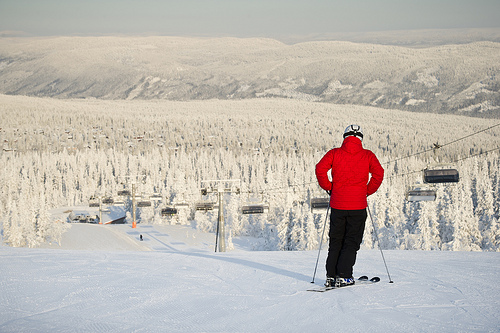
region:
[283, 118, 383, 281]
a person on skis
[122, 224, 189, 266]
a person in the distance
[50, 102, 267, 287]
a snow covered landscape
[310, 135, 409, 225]
a red jacket against the white of snow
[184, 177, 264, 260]
a ski lift in the distance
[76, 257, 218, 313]
fresh white snow on the ground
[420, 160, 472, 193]
a seat on the ski lift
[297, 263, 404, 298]
a pair of skis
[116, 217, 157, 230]
a splash of orange in the distance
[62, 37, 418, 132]
mountains in the distance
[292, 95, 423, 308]
man dressed in red skiing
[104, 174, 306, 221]
ski lift with chairs coming up hill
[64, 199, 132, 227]
ski lodge at bottom of the hill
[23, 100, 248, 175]
snow covered pine trees in the distance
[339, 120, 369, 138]
helmet on a skier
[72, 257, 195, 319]
ski tracks in the snow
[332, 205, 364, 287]
black snow pants on the skier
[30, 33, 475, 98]
snow covered mountain in the distance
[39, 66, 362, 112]
snow covered valley in the distance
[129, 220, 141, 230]
orange cone boundary in the distance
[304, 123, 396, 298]
Person skiing in the snow.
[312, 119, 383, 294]
Red jacket on the person.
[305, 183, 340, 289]
Ski poles in the hand.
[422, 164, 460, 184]
Ski lift bench on the wire.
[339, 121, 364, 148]
White helmet on the woman.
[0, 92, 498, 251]
snow covered trees in the background.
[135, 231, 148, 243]
Person in the background.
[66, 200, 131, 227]
Lodge in the background.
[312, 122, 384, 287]
black snow pants on person.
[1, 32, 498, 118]
Mountains in the background.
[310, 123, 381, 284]
The man is ready to ski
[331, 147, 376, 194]
He is wearing a red jacket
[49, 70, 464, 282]
Snow covers the entire area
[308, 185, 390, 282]
He is holding ski poles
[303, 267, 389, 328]
Skis on his feet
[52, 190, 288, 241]
There are cars down below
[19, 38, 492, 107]
A frozen mountain in the background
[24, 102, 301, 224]
Many snow covered trees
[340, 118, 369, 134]
His helmet is white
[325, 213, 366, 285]
His pants are black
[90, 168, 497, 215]
ski lift cars coming up the mounta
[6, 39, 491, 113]
mountain range on the horizon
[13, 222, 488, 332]
a white ski slope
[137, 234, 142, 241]
person skiing at the bottom of the slope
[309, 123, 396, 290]
skier with a red coat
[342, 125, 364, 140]
white ski helmet with black goggle band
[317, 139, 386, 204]
red ski jacket with hood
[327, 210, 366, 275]
black ski pants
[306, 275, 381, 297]
a pair of snow skis in the snow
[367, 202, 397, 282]
the skier's right pole